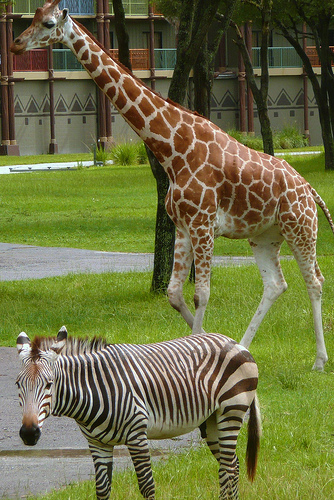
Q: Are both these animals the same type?
A: No, they are giraffes and zebras.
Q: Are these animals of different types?
A: Yes, they are giraffes and zebras.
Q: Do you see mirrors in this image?
A: No, there are no mirrors.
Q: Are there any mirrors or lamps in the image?
A: No, there are no mirrors or lamps.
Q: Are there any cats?
A: No, there are no cats.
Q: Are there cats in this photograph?
A: No, there are no cats.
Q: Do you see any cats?
A: No, there are no cats.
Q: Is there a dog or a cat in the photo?
A: No, there are no cats or dogs.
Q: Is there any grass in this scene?
A: Yes, there is grass.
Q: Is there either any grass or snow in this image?
A: Yes, there is grass.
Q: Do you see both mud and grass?
A: No, there is grass but no mud.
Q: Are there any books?
A: No, there are no books.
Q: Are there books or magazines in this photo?
A: No, there are no books or magazines.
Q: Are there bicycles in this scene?
A: No, there are no bicycles.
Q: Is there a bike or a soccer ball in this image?
A: No, there are no bikes or soccer balls.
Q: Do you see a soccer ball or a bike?
A: No, there are no bikes or soccer balls.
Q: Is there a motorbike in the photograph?
A: No, there are no motorcycles.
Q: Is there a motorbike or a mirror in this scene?
A: No, there are no motorcycles or mirrors.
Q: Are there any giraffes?
A: Yes, there is a giraffe.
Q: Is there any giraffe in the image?
A: Yes, there is a giraffe.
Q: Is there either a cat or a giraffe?
A: Yes, there is a giraffe.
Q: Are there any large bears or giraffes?
A: Yes, there is a large giraffe.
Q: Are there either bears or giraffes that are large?
A: Yes, the giraffe is large.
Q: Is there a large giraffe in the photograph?
A: Yes, there is a large giraffe.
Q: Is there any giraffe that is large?
A: Yes, there is a giraffe that is large.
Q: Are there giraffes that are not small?
A: Yes, there is a large giraffe.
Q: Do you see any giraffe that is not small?
A: Yes, there is a large giraffe.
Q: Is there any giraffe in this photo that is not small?
A: Yes, there is a large giraffe.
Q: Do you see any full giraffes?
A: Yes, there is a full giraffe.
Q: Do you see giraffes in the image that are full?
A: Yes, there is a full giraffe.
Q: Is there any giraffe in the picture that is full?
A: Yes, there is a giraffe that is full.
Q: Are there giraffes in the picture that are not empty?
A: Yes, there is an full giraffe.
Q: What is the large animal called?
A: The animal is a giraffe.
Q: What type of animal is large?
A: The animal is a giraffe.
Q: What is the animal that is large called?
A: The animal is a giraffe.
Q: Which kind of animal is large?
A: The animal is a giraffe.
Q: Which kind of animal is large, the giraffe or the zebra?
A: The giraffe is large.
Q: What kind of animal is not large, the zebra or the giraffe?
A: The zebra is not large.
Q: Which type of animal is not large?
A: The animal is a zebra.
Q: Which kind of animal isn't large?
A: The animal is a zebra.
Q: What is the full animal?
A: The animal is a giraffe.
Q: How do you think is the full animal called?
A: The animal is a giraffe.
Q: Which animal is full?
A: The animal is a giraffe.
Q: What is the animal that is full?
A: The animal is a giraffe.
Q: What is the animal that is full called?
A: The animal is a giraffe.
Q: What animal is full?
A: The animal is a giraffe.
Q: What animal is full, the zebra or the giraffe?
A: The giraffe is full.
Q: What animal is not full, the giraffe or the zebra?
A: The zebra is not full.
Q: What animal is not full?
A: The animal is a zebra.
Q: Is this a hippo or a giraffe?
A: This is a giraffe.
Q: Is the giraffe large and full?
A: Yes, the giraffe is large and full.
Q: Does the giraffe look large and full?
A: Yes, the giraffe is large and full.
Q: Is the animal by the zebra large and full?
A: Yes, the giraffe is large and full.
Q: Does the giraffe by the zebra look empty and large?
A: No, the giraffe is large but full.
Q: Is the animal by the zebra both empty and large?
A: No, the giraffe is large but full.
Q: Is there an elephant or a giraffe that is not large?
A: No, there is a giraffe but it is large.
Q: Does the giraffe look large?
A: Yes, the giraffe is large.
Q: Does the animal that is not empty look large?
A: Yes, the giraffe is large.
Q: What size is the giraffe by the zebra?
A: The giraffe is large.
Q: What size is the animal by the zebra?
A: The giraffe is large.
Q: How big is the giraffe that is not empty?
A: The giraffe is large.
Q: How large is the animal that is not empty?
A: The giraffe is large.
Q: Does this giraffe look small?
A: No, the giraffe is large.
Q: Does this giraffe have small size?
A: No, the giraffe is large.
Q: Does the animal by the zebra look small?
A: No, the giraffe is large.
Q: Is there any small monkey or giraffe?
A: No, there is a giraffe but it is large.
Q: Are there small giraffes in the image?
A: No, there is a giraffe but it is large.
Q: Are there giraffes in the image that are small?
A: No, there is a giraffe but it is large.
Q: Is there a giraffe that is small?
A: No, there is a giraffe but it is large.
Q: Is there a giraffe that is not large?
A: No, there is a giraffe but it is large.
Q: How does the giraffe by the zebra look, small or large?
A: The giraffe is large.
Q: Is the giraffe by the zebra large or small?
A: The giraffe is large.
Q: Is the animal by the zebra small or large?
A: The giraffe is large.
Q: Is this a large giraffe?
A: Yes, this is a large giraffe.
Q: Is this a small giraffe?
A: No, this is a large giraffe.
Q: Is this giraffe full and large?
A: Yes, the giraffe is full and large.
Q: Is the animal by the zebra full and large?
A: Yes, the giraffe is full and large.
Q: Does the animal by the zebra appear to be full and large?
A: Yes, the giraffe is full and large.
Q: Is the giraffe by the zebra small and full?
A: No, the giraffe is full but large.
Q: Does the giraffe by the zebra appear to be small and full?
A: No, the giraffe is full but large.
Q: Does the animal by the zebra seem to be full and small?
A: No, the giraffe is full but large.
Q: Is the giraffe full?
A: Yes, the giraffe is full.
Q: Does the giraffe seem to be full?
A: Yes, the giraffe is full.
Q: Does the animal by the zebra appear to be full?
A: Yes, the giraffe is full.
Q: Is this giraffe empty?
A: No, the giraffe is full.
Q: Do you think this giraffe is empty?
A: No, the giraffe is full.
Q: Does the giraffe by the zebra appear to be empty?
A: No, the giraffe is full.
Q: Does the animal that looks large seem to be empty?
A: No, the giraffe is full.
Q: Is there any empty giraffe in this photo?
A: No, there is a giraffe but it is full.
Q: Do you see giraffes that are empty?
A: No, there is a giraffe but it is full.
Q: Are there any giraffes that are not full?
A: No, there is a giraffe but it is full.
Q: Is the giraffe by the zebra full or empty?
A: The giraffe is full.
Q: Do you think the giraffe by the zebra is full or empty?
A: The giraffe is full.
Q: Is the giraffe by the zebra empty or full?
A: The giraffe is full.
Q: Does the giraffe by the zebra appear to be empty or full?
A: The giraffe is full.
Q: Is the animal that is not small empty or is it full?
A: The giraffe is full.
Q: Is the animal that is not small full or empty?
A: The giraffe is full.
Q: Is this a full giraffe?
A: Yes, this is a full giraffe.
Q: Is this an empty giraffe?
A: No, this is a full giraffe.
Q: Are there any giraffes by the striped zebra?
A: Yes, there is a giraffe by the zebra.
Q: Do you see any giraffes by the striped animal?
A: Yes, there is a giraffe by the zebra.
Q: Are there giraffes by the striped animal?
A: Yes, there is a giraffe by the zebra.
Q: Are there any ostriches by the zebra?
A: No, there is a giraffe by the zebra.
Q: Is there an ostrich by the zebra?
A: No, there is a giraffe by the zebra.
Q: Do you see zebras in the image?
A: Yes, there is a zebra.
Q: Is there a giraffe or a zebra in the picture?
A: Yes, there is a zebra.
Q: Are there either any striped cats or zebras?
A: Yes, there is a striped zebra.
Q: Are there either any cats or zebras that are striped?
A: Yes, the zebra is striped.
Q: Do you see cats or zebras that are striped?
A: Yes, the zebra is striped.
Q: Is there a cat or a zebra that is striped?
A: Yes, the zebra is striped.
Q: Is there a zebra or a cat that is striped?
A: Yes, the zebra is striped.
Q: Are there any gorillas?
A: No, there are no gorillas.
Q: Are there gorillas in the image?
A: No, there are no gorillas.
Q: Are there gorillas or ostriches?
A: No, there are no gorillas or ostriches.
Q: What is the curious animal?
A: The animal is a zebra.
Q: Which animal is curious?
A: The animal is a zebra.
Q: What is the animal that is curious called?
A: The animal is a zebra.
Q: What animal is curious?
A: The animal is a zebra.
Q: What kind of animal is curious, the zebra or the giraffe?
A: The zebra is curious.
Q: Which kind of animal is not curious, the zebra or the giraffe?
A: The giraffe is not curious.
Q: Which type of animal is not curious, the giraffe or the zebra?
A: The giraffe is not curious.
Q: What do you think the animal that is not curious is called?
A: The animal is a giraffe.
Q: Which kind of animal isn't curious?
A: The animal is a giraffe.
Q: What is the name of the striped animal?
A: The animal is a zebra.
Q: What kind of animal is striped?
A: The animal is a zebra.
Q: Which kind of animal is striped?
A: The animal is a zebra.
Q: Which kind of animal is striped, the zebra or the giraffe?
A: The zebra is striped.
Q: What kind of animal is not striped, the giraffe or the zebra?
A: The giraffe is not striped.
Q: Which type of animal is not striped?
A: The animal is a giraffe.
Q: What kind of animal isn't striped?
A: The animal is a giraffe.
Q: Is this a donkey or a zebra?
A: This is a zebra.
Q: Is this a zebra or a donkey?
A: This is a zebra.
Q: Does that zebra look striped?
A: Yes, the zebra is striped.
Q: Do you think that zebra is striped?
A: Yes, the zebra is striped.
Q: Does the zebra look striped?
A: Yes, the zebra is striped.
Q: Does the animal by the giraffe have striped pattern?
A: Yes, the zebra is striped.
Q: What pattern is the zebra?
A: The zebra is striped.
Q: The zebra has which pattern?
A: The zebra is striped.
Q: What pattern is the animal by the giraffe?
A: The zebra is striped.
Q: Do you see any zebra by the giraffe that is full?
A: Yes, there is a zebra by the giraffe.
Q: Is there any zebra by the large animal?
A: Yes, there is a zebra by the giraffe.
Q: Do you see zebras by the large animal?
A: Yes, there is a zebra by the giraffe.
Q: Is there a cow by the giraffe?
A: No, there is a zebra by the giraffe.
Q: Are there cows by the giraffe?
A: No, there is a zebra by the giraffe.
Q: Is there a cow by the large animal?
A: No, there is a zebra by the giraffe.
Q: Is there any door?
A: Yes, there is a door.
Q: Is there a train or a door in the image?
A: Yes, there is a door.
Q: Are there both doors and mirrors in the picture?
A: No, there is a door but no mirrors.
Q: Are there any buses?
A: No, there are no buses.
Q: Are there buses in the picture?
A: No, there are no buses.